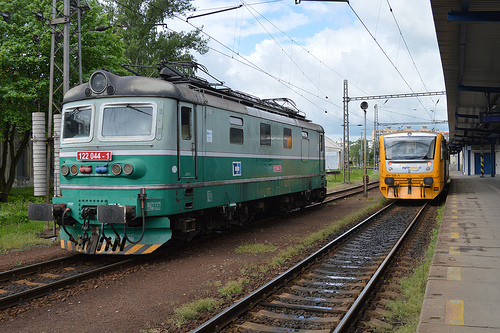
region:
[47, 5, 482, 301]
Two trains are on two tracks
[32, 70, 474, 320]
Two trains are in the photo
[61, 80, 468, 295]
Train tracks are in the photo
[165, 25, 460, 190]
Clouds are in the sky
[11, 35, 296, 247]
Trees are in the background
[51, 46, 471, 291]
One train is green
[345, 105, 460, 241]
One train is yellow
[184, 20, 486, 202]
The sky is blue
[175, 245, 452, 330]
Grass is near the tracks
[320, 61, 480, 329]
A train platform is near the yellow train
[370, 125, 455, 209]
yellow train along side of platform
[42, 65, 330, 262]
aqua train on the train tracks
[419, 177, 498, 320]
train station platform along side of the tracks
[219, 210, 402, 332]
metal train tracks on the ground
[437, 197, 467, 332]
yellow painted lines on platform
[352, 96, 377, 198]
rearview of train traffic sign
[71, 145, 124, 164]
red plate number on aqua train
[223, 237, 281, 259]
patch of green grass in the dirt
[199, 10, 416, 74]
blue sky with white clouds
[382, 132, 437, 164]
front window of yellow train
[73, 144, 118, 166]
a red lisence plate on the train.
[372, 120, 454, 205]
a yellow train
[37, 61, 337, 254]
a green and grey train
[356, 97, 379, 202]
a signal light for the trains.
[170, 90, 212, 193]
A door on the right side of the train.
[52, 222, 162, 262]
black and orange stripes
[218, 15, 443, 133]
Big white fluffy clouds in the sky.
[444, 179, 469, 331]
yellow dotted lines on the sidewalk.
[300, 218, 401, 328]
Water on the railroad tracks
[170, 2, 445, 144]
lots of wires above the trains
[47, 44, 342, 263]
A green and blue train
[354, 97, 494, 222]
An orange train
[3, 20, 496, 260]
A green train and an orange train next to eachother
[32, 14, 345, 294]
A green and blue train on tracks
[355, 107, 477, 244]
An orange train on tracks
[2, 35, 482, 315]
Trains on train tracks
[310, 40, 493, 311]
Orange train at a train stop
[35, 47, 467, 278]
Trains outside on tracks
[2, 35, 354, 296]
Green train outside on tracks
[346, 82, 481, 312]
Orange train outside on tracks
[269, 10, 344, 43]
this is the sky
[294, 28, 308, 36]
the sky is blue in color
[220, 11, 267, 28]
this is a cloud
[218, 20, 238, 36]
the cloud is white in color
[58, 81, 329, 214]
this is a train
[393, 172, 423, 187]
the train is yellow in color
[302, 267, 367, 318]
this is a railway line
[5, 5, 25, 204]
this is a tree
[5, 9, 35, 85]
the leaves are green in color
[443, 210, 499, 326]
this is a pavement